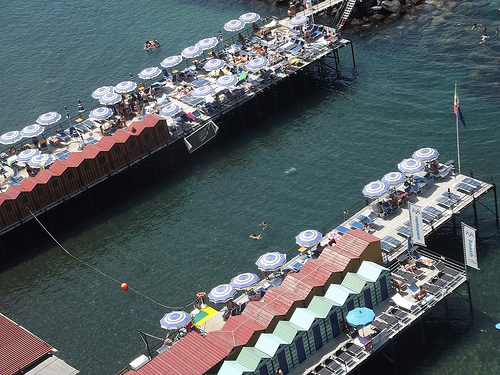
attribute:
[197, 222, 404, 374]
cabanas — red, blue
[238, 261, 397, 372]
huts — green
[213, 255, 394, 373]
structures — blue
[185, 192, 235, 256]
water — green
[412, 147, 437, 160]
umbrella — open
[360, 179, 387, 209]
umbrella — blue, white striped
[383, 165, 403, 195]
umbrella — blue, white striped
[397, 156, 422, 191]
umbrella — blue, white striped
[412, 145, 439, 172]
umbrella — blue, white striped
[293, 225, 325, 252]
umbrella — blue, white striped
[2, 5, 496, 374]
water — green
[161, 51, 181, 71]
umbrella — light aqua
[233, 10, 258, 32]
umbrellas — gray, white